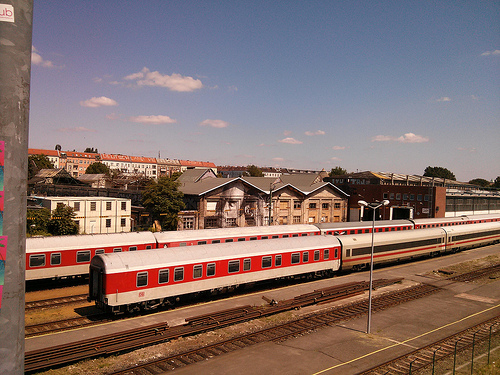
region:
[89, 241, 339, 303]
a red and silver train car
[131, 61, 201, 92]
a fluffy white cloud in the sky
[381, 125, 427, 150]
a fluffy white cloud in the sky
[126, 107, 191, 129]
a fluffy white cloud in the sky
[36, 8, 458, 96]
a clear blue sky overhead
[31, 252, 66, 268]
dark windows in a train car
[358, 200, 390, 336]
a street light in the train yard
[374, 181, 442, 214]
a brick building with lots of windows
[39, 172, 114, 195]
the black roof on building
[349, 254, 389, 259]
a thin red stripe on the side of the train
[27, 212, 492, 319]
Train cars on two rows of the rail.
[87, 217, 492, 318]
Train car with red and white colored front cabin.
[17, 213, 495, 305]
A long train car beside another with red and white colors.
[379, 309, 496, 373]
Perimeter fence in the railway station.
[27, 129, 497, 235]
Various buildings on the side of the railway station.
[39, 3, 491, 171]
A clear blue sky with white clouds.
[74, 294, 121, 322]
Shadow cast by the head of a train bus.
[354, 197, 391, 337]
Lights on the railway station.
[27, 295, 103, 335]
Part of tracks in the railway station.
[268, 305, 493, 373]
Murram road in the station with white lines.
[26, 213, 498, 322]
two trains on a train tracks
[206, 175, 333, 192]
the roofs of a buildings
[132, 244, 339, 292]
the windows of a train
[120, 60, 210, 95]
a cloud in the sky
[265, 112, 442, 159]
clouds in the sky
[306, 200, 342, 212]
the windows of a building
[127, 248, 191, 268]
the roof of a train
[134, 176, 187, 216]
the trees by a building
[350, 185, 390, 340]
a pole light by train tracks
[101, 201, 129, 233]
the window of a building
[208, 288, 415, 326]
train tracks are rusty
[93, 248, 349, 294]
windows on train car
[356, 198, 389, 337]
light post near train track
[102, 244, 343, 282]
red stripe on train car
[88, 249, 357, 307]
train car is red and silver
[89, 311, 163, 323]
yellow caution line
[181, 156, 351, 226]
housing development near train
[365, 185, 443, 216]
red brick building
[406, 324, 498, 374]
fence post near railway line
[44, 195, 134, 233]
white building behind train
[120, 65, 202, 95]
small cloud in the sky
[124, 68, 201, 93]
a white cloud in the sky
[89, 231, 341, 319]
red and white passenger car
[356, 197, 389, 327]
two street lights mounted on one pole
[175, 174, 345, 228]
building by the train tracks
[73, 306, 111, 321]
shadow of the passenger car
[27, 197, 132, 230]
white building next to tracks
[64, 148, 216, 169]
red roofed buildings in the distance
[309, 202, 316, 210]
a window in a building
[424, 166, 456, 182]
tree behind a building